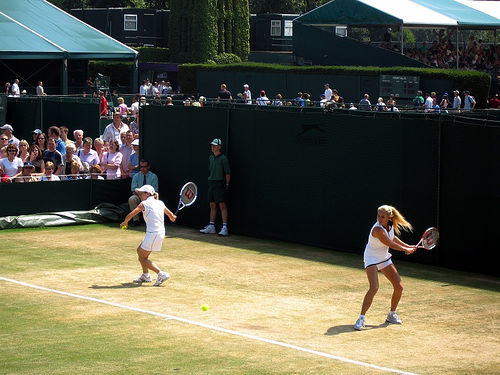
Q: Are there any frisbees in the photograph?
A: No, there are no frisbees.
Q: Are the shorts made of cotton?
A: Yes, the shorts are made of cotton.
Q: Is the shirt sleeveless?
A: Yes, the shirt is sleeveless.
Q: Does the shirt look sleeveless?
A: Yes, the shirt is sleeveless.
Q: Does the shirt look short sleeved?
A: No, the shirt is sleeveless.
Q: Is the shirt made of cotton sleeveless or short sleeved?
A: The shirt is sleeveless.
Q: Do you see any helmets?
A: No, there are no helmets.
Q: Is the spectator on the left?
A: Yes, the spectator is on the left of the image.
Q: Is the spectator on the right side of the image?
A: No, the spectator is on the left of the image.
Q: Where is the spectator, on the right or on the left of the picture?
A: The spectator is on the left of the image.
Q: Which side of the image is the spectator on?
A: The spectator is on the left of the image.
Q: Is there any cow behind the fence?
A: No, there is a spectator behind the fence.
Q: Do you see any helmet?
A: No, there are no helmets.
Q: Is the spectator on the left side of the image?
A: Yes, the spectator is on the left of the image.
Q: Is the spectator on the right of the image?
A: No, the spectator is on the left of the image.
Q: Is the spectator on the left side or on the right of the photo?
A: The spectator is on the left of the image.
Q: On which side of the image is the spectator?
A: The spectator is on the left of the image.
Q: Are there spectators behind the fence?
A: Yes, there is a spectator behind the fence.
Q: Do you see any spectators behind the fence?
A: Yes, there is a spectator behind the fence.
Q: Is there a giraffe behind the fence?
A: No, there is a spectator behind the fence.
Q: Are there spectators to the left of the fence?
A: Yes, there is a spectator to the left of the fence.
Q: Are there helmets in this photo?
A: No, there are no helmets.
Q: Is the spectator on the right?
A: No, the spectator is on the left of the image.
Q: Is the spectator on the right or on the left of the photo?
A: The spectator is on the left of the image.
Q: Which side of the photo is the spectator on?
A: The spectator is on the left of the image.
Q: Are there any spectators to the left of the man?
A: Yes, there is a spectator to the left of the man.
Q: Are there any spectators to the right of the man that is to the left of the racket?
A: No, the spectator is to the left of the man.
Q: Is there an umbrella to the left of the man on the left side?
A: No, there is a spectator to the left of the man.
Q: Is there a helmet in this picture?
A: No, there are no helmets.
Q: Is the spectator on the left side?
A: Yes, the spectator is on the left of the image.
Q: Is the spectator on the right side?
A: No, the spectator is on the left of the image.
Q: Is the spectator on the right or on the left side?
A: The spectator is on the left of the image.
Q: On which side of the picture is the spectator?
A: The spectator is on the left of the image.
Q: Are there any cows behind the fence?
A: No, there is a spectator behind the fence.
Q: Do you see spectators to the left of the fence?
A: Yes, there is a spectator to the left of the fence.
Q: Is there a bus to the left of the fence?
A: No, there is a spectator to the left of the fence.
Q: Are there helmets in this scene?
A: No, there are no helmets.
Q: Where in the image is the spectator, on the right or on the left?
A: The spectator is on the left of the image.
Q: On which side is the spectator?
A: The spectator is on the left of the image.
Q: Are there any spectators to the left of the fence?
A: Yes, there is a spectator to the left of the fence.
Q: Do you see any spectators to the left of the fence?
A: Yes, there is a spectator to the left of the fence.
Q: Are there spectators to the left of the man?
A: Yes, there is a spectator to the left of the man.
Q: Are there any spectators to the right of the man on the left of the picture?
A: No, the spectator is to the left of the man.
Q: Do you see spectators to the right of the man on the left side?
A: No, the spectator is to the left of the man.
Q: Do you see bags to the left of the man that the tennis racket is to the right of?
A: No, there is a spectator to the left of the man.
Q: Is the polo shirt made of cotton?
A: Yes, the polo shirt is made of cotton.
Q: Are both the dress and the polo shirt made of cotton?
A: Yes, both the dress and the polo shirt are made of cotton.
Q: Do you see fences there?
A: Yes, there is a fence.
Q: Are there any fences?
A: Yes, there is a fence.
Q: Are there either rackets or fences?
A: Yes, there is a fence.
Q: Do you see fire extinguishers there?
A: No, there are no fire extinguishers.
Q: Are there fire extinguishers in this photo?
A: No, there are no fire extinguishers.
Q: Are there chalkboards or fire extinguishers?
A: No, there are no fire extinguishers or chalkboards.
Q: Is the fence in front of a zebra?
A: No, the fence is in front of a spectator.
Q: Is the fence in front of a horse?
A: No, the fence is in front of a spectator.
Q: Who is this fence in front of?
A: The fence is in front of the spectator.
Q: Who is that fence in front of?
A: The fence is in front of the spectator.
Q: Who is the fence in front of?
A: The fence is in front of the spectator.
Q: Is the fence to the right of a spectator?
A: Yes, the fence is to the right of a spectator.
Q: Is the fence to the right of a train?
A: No, the fence is to the right of a spectator.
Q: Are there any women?
A: Yes, there is a woman.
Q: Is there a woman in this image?
A: Yes, there is a woman.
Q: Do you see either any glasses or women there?
A: Yes, there is a woman.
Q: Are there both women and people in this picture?
A: Yes, there are both a woman and people.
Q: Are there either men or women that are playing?
A: Yes, the woman is playing.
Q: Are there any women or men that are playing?
A: Yes, the woman is playing.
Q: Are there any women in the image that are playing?
A: Yes, there is a woman that is playing.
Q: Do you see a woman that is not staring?
A: Yes, there is a woman that is playing .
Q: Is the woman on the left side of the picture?
A: Yes, the woman is on the left of the image.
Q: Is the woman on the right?
A: No, the woman is on the left of the image.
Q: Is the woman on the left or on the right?
A: The woman is on the left of the image.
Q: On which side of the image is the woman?
A: The woman is on the left of the image.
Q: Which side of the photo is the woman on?
A: The woman is on the left of the image.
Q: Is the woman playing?
A: Yes, the woman is playing.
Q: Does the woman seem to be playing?
A: Yes, the woman is playing.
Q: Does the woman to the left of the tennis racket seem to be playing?
A: Yes, the woman is playing.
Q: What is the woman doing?
A: The woman is playing.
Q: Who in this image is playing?
A: The woman is playing.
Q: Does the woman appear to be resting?
A: No, the woman is playing.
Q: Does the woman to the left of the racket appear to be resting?
A: No, the woman is playing.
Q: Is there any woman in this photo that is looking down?
A: No, there is a woman but she is playing.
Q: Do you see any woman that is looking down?
A: No, there is a woman but she is playing.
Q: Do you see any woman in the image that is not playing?
A: No, there is a woman but she is playing.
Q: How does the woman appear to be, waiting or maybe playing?
A: The woman is playing.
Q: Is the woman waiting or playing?
A: The woman is playing.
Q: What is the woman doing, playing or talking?
A: The woman is playing.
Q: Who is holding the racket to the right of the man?
A: The woman is holding the racket.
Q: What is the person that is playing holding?
A: The woman is holding the racket.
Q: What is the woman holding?
A: The woman is holding the racket.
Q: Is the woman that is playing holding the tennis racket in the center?
A: Yes, the woman is holding the tennis racket.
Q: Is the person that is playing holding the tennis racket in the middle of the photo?
A: Yes, the woman is holding the tennis racket.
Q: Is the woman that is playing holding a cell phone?
A: No, the woman is holding the tennis racket.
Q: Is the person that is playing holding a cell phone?
A: No, the woman is holding the tennis racket.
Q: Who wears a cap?
A: The woman wears a cap.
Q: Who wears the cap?
A: The woman wears a cap.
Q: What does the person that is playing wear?
A: The woman wears a cap.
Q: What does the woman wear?
A: The woman wears a cap.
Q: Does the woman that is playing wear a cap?
A: Yes, the woman wears a cap.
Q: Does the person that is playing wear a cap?
A: Yes, the woman wears a cap.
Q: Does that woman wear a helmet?
A: No, the woman wears a cap.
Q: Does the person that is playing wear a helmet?
A: No, the woman wears a cap.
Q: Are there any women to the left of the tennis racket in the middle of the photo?
A: Yes, there is a woman to the left of the racket.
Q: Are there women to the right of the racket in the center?
A: No, the woman is to the left of the racket.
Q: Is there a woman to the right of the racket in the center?
A: No, the woman is to the left of the racket.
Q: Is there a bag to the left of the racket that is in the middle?
A: No, there is a woman to the left of the racket.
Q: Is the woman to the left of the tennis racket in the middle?
A: Yes, the woman is to the left of the tennis racket.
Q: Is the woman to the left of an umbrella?
A: No, the woman is to the left of the tennis racket.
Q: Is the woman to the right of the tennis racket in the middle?
A: No, the woman is to the left of the tennis racket.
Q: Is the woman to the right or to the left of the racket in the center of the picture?
A: The woman is to the left of the tennis racket.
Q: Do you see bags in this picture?
A: No, there are no bags.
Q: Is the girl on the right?
A: Yes, the girl is on the right of the image.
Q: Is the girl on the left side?
A: No, the girl is on the right of the image.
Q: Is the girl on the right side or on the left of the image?
A: The girl is on the right of the image.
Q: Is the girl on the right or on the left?
A: The girl is on the right of the image.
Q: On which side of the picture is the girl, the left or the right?
A: The girl is on the right of the image.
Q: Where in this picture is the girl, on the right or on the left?
A: The girl is on the right of the image.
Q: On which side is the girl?
A: The girl is on the right of the image.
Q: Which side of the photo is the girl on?
A: The girl is on the right of the image.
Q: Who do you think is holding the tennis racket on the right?
A: The girl is holding the tennis racket.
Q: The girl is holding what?
A: The girl is holding the tennis racket.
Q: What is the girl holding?
A: The girl is holding the tennis racket.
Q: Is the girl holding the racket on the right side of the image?
A: Yes, the girl is holding the tennis racket.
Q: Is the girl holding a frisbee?
A: No, the girl is holding the tennis racket.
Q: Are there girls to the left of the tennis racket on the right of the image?
A: Yes, there is a girl to the left of the racket.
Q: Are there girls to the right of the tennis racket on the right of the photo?
A: No, the girl is to the left of the tennis racket.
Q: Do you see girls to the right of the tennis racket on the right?
A: No, the girl is to the left of the tennis racket.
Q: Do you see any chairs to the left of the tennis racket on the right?
A: No, there is a girl to the left of the tennis racket.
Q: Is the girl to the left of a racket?
A: Yes, the girl is to the left of a racket.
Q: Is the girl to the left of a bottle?
A: No, the girl is to the left of a racket.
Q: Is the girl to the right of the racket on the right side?
A: No, the girl is to the left of the racket.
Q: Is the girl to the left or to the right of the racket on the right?
A: The girl is to the left of the racket.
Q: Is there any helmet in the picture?
A: No, there are no helmets.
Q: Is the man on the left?
A: Yes, the man is on the left of the image.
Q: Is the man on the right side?
A: No, the man is on the left of the image.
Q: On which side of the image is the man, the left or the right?
A: The man is on the left of the image.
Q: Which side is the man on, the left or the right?
A: The man is on the left of the image.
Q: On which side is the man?
A: The man is on the left of the image.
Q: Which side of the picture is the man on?
A: The man is on the left of the image.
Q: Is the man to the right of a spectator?
A: Yes, the man is to the right of a spectator.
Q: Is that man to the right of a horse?
A: No, the man is to the right of a spectator.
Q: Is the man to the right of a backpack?
A: No, the man is to the right of a spectator.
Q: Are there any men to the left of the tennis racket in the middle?
A: Yes, there is a man to the left of the racket.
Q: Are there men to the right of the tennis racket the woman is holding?
A: No, the man is to the left of the racket.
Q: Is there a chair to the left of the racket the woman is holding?
A: No, there is a man to the left of the tennis racket.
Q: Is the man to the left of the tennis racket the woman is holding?
A: Yes, the man is to the left of the tennis racket.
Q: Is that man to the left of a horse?
A: No, the man is to the left of the tennis racket.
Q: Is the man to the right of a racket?
A: No, the man is to the left of a racket.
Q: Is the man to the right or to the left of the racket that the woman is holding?
A: The man is to the left of the racket.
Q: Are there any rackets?
A: Yes, there is a racket.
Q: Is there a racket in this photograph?
A: Yes, there is a racket.